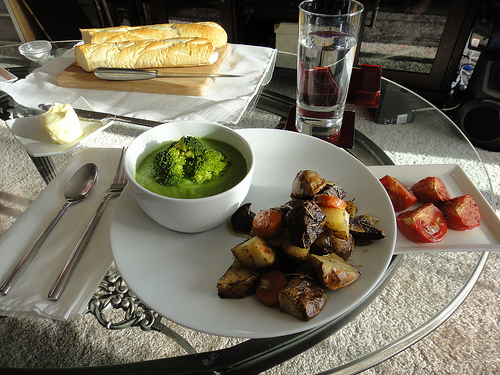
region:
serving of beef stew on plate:
[215, 168, 387, 320]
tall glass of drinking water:
[295, 1, 365, 141]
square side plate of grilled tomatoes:
[364, 163, 499, 254]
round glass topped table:
[1, 37, 494, 373]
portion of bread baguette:
[72, 21, 229, 70]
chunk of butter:
[9, 101, 84, 144]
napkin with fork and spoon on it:
[2, 145, 129, 326]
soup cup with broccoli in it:
[120, 117, 257, 234]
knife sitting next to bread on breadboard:
[92, 66, 244, 82]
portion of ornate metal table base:
[82, 266, 200, 355]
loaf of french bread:
[65, 16, 245, 77]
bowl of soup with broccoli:
[122, 100, 267, 231]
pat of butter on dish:
[17, 88, 93, 148]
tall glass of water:
[286, 2, 368, 144]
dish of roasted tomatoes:
[375, 156, 492, 246]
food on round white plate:
[98, 111, 391, 323]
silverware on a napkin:
[15, 134, 139, 304]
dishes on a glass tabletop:
[6, 41, 477, 336]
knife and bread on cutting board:
[56, 22, 263, 101]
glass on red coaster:
[279, 1, 365, 157]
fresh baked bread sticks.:
[67, 13, 248, 73]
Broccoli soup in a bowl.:
[111, 108, 281, 234]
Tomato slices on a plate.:
[374, 170, 477, 245]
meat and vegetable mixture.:
[218, 167, 363, 338]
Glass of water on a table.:
[282, 0, 369, 156]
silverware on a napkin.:
[0, 156, 109, 322]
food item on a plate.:
[19, 87, 108, 154]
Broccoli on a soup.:
[152, 122, 205, 189]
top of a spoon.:
[66, 158, 94, 203]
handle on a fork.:
[41, 222, 91, 308]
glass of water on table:
[274, 0, 371, 152]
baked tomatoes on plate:
[355, 125, 498, 270]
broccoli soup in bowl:
[110, 119, 270, 224]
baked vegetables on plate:
[207, 162, 421, 337]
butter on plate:
[4, 84, 136, 160]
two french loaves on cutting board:
[55, 9, 265, 99]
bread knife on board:
[92, 42, 271, 109]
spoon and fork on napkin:
[0, 132, 128, 353]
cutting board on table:
[42, 43, 256, 118]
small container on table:
[10, 30, 62, 65]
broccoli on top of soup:
[157, 137, 227, 194]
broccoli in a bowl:
[154, 131, 231, 188]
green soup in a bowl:
[132, 135, 253, 206]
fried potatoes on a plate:
[211, 155, 391, 332]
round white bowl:
[118, 112, 256, 227]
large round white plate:
[95, 121, 400, 342]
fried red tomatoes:
[357, 160, 497, 268]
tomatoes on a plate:
[364, 155, 495, 262]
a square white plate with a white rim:
[362, 150, 496, 270]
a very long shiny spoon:
[4, 125, 108, 319]